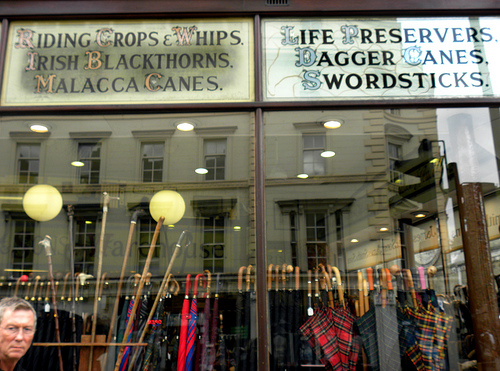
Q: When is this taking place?
A: Daytime.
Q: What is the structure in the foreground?
A: Storefront.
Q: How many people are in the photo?
A: One.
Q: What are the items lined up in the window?
A: Umbrellas.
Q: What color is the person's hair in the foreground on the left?
A: Grey and black.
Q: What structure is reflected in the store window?
A: Building.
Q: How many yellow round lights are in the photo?
A: Two.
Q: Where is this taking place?
A: In front of the store.